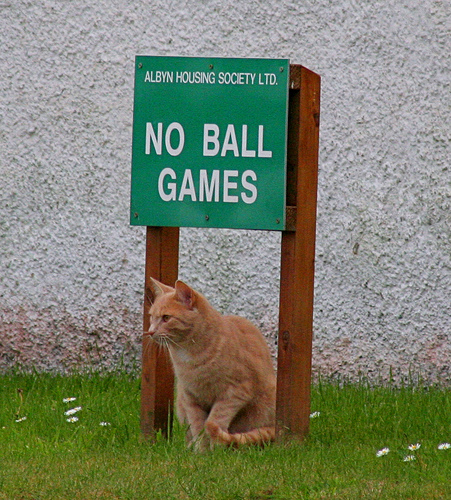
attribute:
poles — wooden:
[121, 40, 324, 454]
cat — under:
[138, 262, 288, 456]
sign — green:
[72, 32, 352, 247]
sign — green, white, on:
[127, 54, 291, 231]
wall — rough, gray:
[2, 2, 448, 384]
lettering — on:
[154, 166, 257, 209]